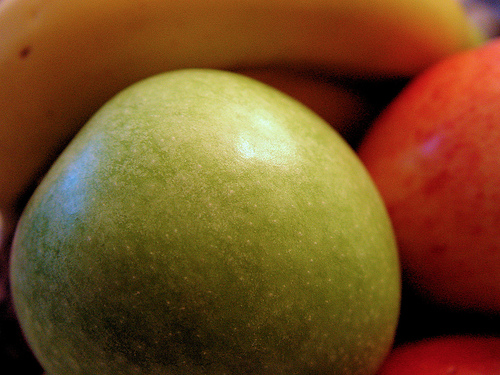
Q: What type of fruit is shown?
A: Apples.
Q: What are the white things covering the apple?
A: Spots.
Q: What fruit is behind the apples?
A: A banana.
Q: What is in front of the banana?
A: An apple.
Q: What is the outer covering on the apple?
A: Skin.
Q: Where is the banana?
A: Behind the apples.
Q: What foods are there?
A: Fruit.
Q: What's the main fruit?
A: Apple.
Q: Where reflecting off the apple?
A: Light.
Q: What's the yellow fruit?
A: Banana.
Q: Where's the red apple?
A: On right.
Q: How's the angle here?
A: Close-up.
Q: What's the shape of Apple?
A: Round.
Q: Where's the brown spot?
A: Banana.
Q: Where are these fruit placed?
A: In a bunch.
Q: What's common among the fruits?
A: All sweet.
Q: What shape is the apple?
A: Round.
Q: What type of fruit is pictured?
A: An apple.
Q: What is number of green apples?
A: One.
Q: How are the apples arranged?
A: They are stacked.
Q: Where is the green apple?
A: On the top.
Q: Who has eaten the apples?
A: The apples have not been eaten.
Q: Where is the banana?
A: Behind the green apple.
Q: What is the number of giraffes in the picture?
A: Zero.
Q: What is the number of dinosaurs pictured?
A: Zero.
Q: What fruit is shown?
A: A apple.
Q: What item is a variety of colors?
A: A apple.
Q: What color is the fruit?
A: Green, yellow and red.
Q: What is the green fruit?
A: Apple.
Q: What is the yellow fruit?
A: Banana.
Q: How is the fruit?
A: Ripe.